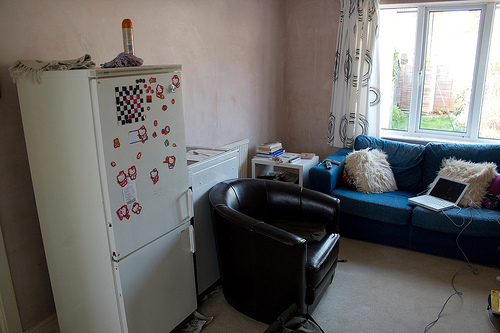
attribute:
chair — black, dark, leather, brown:
[205, 175, 342, 327]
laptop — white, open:
[408, 175, 469, 212]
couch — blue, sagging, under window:
[307, 135, 499, 271]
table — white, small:
[250, 152, 321, 188]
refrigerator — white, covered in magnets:
[10, 62, 201, 332]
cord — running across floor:
[423, 205, 482, 332]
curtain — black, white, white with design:
[324, 1, 379, 151]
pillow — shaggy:
[431, 154, 498, 209]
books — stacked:
[255, 140, 288, 159]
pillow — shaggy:
[343, 146, 398, 196]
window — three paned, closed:
[367, 0, 499, 145]